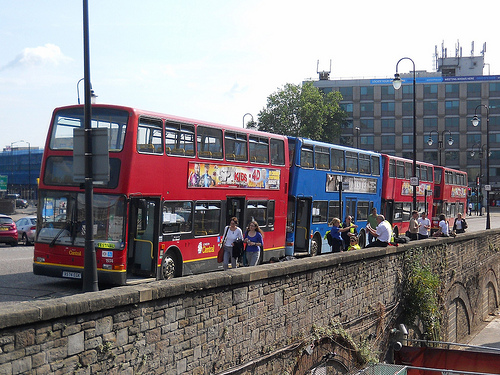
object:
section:
[285, 132, 383, 259]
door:
[122, 196, 159, 282]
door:
[292, 199, 313, 251]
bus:
[443, 170, 467, 215]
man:
[416, 208, 431, 238]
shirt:
[415, 217, 434, 232]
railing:
[110, 229, 155, 268]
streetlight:
[392, 56, 418, 212]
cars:
[0, 212, 36, 250]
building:
[304, 68, 498, 206]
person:
[217, 215, 244, 272]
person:
[241, 216, 266, 272]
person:
[329, 212, 352, 257]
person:
[341, 214, 360, 254]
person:
[358, 210, 390, 252]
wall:
[0, 225, 500, 374]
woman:
[211, 213, 241, 263]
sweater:
[225, 221, 235, 244]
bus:
[287, 135, 387, 257]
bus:
[380, 145, 437, 231]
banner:
[327, 175, 379, 194]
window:
[163, 120, 194, 158]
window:
[159, 197, 196, 238]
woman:
[244, 219, 266, 260]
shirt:
[240, 232, 265, 251]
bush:
[388, 258, 446, 348]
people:
[455, 208, 464, 237]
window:
[135, 115, 164, 153]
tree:
[254, 86, 341, 129]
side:
[126, 112, 293, 258]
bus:
[31, 104, 294, 287]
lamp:
[393, 56, 418, 211]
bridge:
[0, 227, 498, 372]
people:
[403, 210, 421, 240]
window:
[248, 132, 270, 166]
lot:
[2, 198, 43, 294]